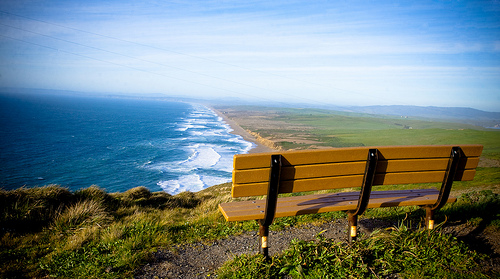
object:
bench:
[218, 146, 483, 259]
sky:
[1, 1, 498, 103]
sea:
[1, 87, 252, 196]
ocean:
[0, 91, 203, 187]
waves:
[176, 122, 222, 171]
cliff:
[0, 165, 496, 278]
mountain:
[367, 104, 497, 119]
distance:
[1, 1, 496, 194]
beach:
[212, 106, 274, 155]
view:
[1, 2, 497, 194]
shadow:
[361, 200, 499, 232]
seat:
[217, 188, 454, 222]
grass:
[3, 200, 130, 263]